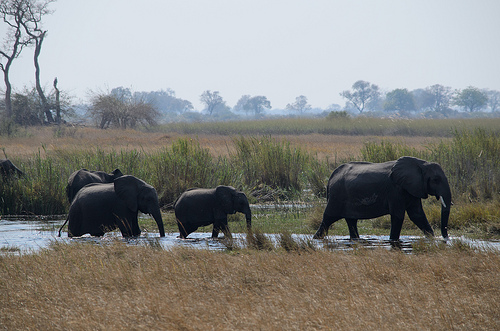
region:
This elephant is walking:
[326, 155, 455, 245]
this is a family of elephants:
[68, 159, 463, 248]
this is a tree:
[287, 89, 314, 121]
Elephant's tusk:
[436, 192, 450, 208]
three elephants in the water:
[61, 160, 253, 256]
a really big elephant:
[323, 156, 455, 256]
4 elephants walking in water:
[56, 160, 462, 263]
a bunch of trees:
[329, 80, 497, 131]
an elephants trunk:
[439, 196, 456, 242]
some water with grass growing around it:
[3, 225, 498, 260]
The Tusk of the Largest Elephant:
[434, 194, 448, 210]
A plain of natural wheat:
[2, 253, 497, 328]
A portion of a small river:
[2, 214, 54, 250]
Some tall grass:
[233, 143, 324, 186]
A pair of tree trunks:
[25, 35, 63, 130]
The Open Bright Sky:
[61, 0, 499, 84]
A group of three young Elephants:
[61, 166, 262, 248]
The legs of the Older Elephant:
[314, 206, 435, 258]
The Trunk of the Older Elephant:
[438, 183, 453, 238]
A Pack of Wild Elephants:
[64, 140, 457, 260]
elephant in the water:
[171, 182, 258, 239]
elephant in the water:
[305, 160, 458, 245]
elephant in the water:
[69, 188, 161, 246]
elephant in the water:
[63, 160, 117, 185]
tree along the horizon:
[248, 95, 268, 123]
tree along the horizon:
[285, 88, 312, 118]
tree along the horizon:
[393, 87, 415, 116]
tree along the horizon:
[451, 83, 485, 114]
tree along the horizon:
[92, 94, 146, 132]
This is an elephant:
[299, 152, 476, 263]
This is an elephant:
[167, 177, 263, 244]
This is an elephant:
[52, 175, 170, 247]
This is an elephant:
[57, 155, 123, 204]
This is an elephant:
[0, 139, 35, 201]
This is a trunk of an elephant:
[429, 166, 461, 254]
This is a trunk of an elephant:
[236, 195, 265, 246]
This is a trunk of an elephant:
[146, 192, 172, 247]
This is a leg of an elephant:
[408, 193, 443, 248]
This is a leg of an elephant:
[383, 195, 410, 246]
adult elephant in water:
[319, 158, 451, 253]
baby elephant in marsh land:
[171, 185, 255, 251]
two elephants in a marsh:
[60, 165, 169, 249]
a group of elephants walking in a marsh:
[58, 147, 460, 256]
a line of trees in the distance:
[103, 83, 498, 115]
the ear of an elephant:
[390, 153, 428, 199]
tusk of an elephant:
[438, 196, 445, 208]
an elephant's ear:
[112, 175, 140, 212]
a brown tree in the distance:
[90, 94, 153, 130]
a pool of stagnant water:
[2, 216, 57, 258]